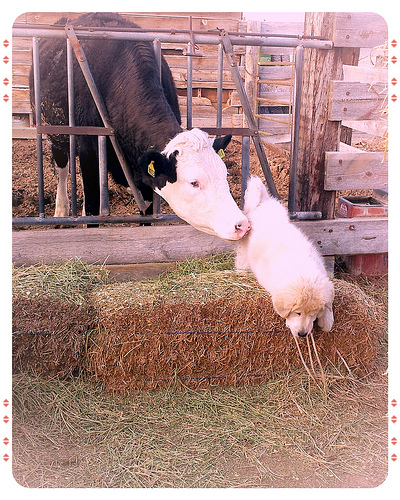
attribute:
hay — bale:
[90, 268, 378, 392]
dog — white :
[264, 228, 337, 322]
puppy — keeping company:
[234, 173, 335, 338]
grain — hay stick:
[12, 258, 385, 386]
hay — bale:
[5, 271, 388, 390]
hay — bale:
[16, 265, 97, 375]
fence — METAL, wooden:
[12, 25, 335, 226]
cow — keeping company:
[25, 9, 251, 245]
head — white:
[139, 128, 251, 243]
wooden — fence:
[299, 54, 323, 140]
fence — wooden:
[294, 25, 383, 214]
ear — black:
[212, 133, 232, 151]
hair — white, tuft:
[161, 126, 214, 159]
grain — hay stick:
[108, 296, 245, 361]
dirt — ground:
[263, 451, 351, 480]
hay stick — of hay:
[278, 326, 356, 405]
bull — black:
[29, 25, 263, 252]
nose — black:
[298, 327, 306, 337]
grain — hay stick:
[261, 377, 329, 433]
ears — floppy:
[272, 276, 302, 327]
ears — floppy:
[317, 271, 339, 339]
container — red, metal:
[330, 190, 387, 280]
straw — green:
[14, 374, 388, 487]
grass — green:
[13, 375, 387, 486]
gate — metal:
[13, 25, 330, 221]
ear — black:
[136, 150, 167, 176]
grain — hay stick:
[28, 377, 365, 457]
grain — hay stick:
[37, 377, 365, 469]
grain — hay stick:
[159, 393, 239, 421]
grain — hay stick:
[166, 409, 254, 441]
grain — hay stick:
[216, 406, 278, 445]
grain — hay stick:
[193, 401, 283, 439]